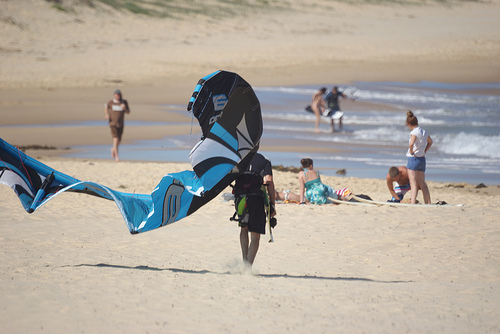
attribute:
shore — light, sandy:
[308, 234, 409, 315]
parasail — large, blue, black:
[6, 54, 286, 272]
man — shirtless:
[386, 164, 409, 202]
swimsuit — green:
[303, 168, 329, 202]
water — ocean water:
[48, 83, 496, 186]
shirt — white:
[406, 127, 429, 157]